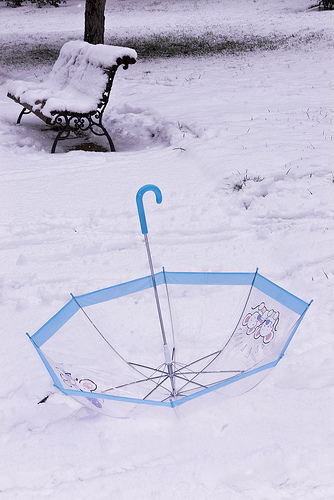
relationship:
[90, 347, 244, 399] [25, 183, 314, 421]
metal framework of blue umbrella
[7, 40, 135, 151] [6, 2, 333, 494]
bench covered in snow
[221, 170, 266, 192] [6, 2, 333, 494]
dark grass poking through snow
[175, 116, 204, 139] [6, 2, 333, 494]
dark grass poking through snow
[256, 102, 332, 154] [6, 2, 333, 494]
dark grass poking through snow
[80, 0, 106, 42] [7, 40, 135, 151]
tree trunk behind bench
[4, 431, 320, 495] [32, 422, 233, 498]
snow on ground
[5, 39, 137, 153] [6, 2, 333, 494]
bench in snow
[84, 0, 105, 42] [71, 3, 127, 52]
tree trunk of tree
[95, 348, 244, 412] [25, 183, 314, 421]
wires on blue umbrella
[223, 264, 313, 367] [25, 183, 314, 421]
wires on blue umbrella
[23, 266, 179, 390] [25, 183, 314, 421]
wires on blue umbrella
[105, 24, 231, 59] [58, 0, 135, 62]
grass around tree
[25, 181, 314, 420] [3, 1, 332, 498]
blue umbrella on ground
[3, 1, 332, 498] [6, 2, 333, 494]
ground covered in snow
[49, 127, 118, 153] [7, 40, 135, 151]
leg of bench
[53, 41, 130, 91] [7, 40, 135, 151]
backrest of bench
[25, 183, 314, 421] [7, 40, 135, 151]
blue umbrella next to bench